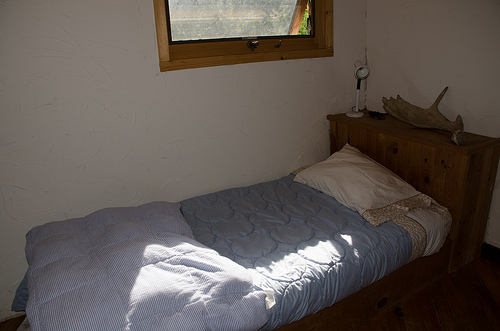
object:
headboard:
[323, 109, 499, 275]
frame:
[157, 34, 335, 74]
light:
[130, 235, 341, 314]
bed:
[10, 161, 455, 330]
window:
[151, 0, 333, 73]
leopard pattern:
[360, 193, 432, 227]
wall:
[0, 0, 357, 330]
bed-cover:
[180, 160, 451, 330]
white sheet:
[407, 203, 453, 258]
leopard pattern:
[394, 216, 428, 264]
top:
[323, 110, 499, 155]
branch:
[430, 84, 450, 110]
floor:
[272, 257, 500, 331]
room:
[0, 0, 499, 330]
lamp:
[343, 59, 371, 119]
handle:
[250, 38, 265, 48]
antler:
[379, 85, 467, 146]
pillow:
[290, 143, 438, 227]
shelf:
[324, 110, 499, 276]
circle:
[260, 184, 298, 205]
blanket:
[23, 200, 271, 331]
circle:
[281, 197, 325, 219]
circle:
[229, 234, 280, 258]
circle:
[330, 222, 381, 251]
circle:
[266, 218, 316, 245]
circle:
[245, 203, 292, 230]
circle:
[230, 198, 270, 215]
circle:
[253, 251, 308, 281]